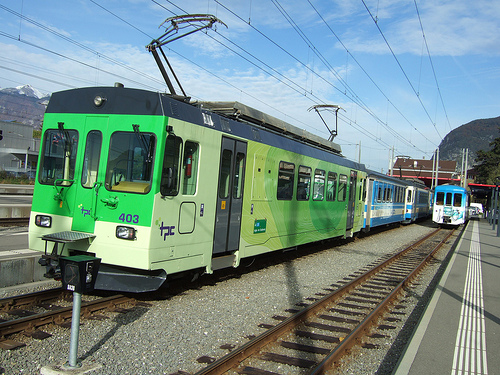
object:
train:
[424, 179, 472, 230]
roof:
[388, 157, 454, 181]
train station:
[4, 92, 498, 372]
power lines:
[88, 0, 131, 28]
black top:
[43, 83, 394, 180]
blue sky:
[0, 0, 497, 94]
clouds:
[442, 0, 499, 47]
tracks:
[390, 235, 455, 248]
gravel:
[158, 331, 172, 344]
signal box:
[56, 254, 104, 294]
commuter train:
[25, 83, 435, 303]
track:
[4, 291, 31, 339]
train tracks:
[286, 300, 408, 324]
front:
[31, 109, 166, 229]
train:
[25, 80, 425, 297]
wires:
[256, 30, 283, 48]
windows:
[276, 161, 294, 200]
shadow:
[283, 262, 303, 300]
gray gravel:
[6, 354, 25, 368]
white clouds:
[343, 26, 366, 44]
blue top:
[434, 184, 464, 193]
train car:
[359, 175, 408, 237]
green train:
[28, 84, 369, 302]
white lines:
[453, 338, 461, 358]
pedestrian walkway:
[396, 216, 498, 372]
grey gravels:
[182, 341, 194, 349]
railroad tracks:
[202, 348, 352, 369]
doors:
[211, 136, 236, 257]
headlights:
[35, 215, 51, 228]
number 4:
[119, 213, 125, 222]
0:
[126, 214, 132, 223]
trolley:
[21, 78, 428, 301]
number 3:
[133, 214, 140, 223]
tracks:
[355, 264, 413, 271]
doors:
[226, 139, 250, 254]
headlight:
[116, 226, 135, 240]